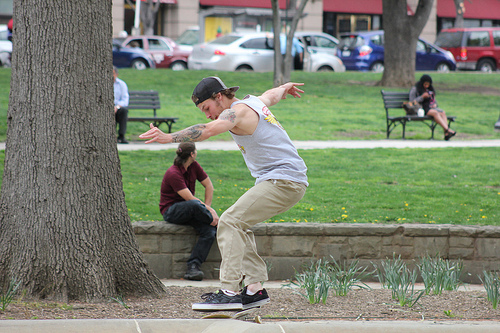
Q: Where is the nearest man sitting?
A: On wall.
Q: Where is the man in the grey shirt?
A: On skateboard.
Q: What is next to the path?
A: Benches.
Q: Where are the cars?
A: In the parking lot.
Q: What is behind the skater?
A: Little plants.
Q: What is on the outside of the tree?
A: Bark.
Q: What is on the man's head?
A: A baseball hat.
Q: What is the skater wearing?
A: A tank top and pants.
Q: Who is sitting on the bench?
A: A woman.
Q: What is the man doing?
A: Skateboarding.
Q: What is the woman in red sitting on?
A: A stone wall.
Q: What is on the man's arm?
A: Tattoos.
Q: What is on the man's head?
A: Baseball cap.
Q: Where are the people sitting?
A: Benches.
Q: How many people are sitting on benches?
A: Two.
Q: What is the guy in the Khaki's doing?
A: Skateboarding.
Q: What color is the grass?
A: Green.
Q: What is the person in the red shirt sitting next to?
A: A tree.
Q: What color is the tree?
A: Brown.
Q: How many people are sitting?
A: Three.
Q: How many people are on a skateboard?
A: One.